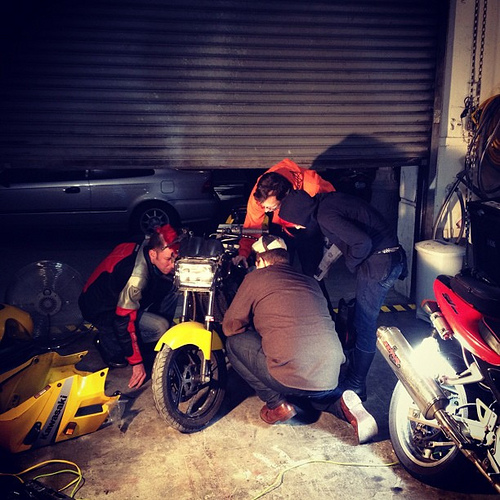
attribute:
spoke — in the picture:
[167, 351, 218, 415]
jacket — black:
[286, 185, 398, 297]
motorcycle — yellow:
[131, 232, 306, 414]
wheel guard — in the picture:
[135, 321, 272, 393]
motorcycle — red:
[353, 260, 498, 482]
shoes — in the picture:
[255, 388, 387, 449]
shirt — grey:
[221, 268, 343, 390]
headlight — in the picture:
[170, 261, 221, 290]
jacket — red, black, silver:
[75, 231, 162, 365]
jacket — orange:
[231, 159, 338, 256]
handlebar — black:
[212, 220, 269, 237]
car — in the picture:
[5, 172, 254, 240]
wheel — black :
[378, 307, 499, 489]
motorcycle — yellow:
[92, 267, 334, 465]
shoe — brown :
[256, 397, 297, 429]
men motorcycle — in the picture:
[76, 157, 407, 446]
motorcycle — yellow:
[147, 230, 258, 435]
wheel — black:
[148, 320, 233, 434]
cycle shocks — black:
[179, 290, 217, 319]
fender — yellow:
[152, 316, 224, 360]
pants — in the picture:
[228, 339, 296, 425]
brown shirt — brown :
[218, 261, 349, 393]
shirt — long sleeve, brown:
[217, 262, 347, 403]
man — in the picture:
[70, 209, 227, 418]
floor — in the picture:
[0, 335, 480, 499]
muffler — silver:
[366, 307, 473, 424]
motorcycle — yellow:
[146, 200, 273, 438]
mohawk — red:
[154, 221, 178, 251]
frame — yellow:
[150, 310, 215, 357]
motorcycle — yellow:
[147, 220, 272, 429]